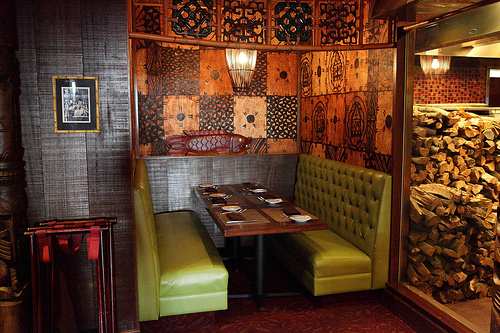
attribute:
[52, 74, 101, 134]
picture —  wall's, framed, hanging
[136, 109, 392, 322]
booth — green,  for seating,  in restaurant, in restaurant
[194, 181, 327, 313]
table — wood,  set,  for six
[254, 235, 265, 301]
pole — black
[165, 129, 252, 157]
fish — red,  decoration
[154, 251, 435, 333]
carpet — red,  deep red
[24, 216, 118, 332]
basket — red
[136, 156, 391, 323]
seat — green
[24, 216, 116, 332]
tray holder — red,  tray's,  of food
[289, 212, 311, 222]
plate — white,  white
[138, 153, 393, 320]
bench — green, w/ shadow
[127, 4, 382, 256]
wall —  brown,  w/ dark wood paneling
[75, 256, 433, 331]
floor —  brown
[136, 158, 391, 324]
benches — green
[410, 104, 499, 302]
logs —  wooden, in stack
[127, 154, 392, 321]
booth — green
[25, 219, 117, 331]
tray —  wooden,  folding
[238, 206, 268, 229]
placemat —  brown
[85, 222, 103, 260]
stands —  folding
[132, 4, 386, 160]
wallpaper —  exotic,  brown , of print